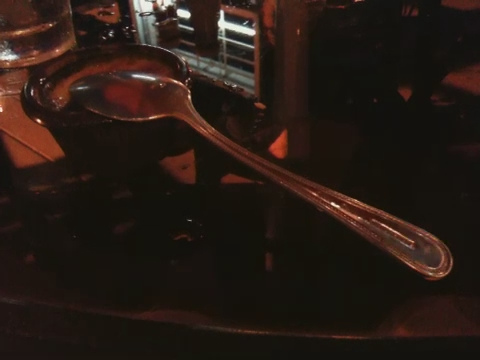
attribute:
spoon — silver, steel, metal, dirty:
[61, 61, 479, 285]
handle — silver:
[247, 145, 459, 286]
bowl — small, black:
[64, 51, 173, 68]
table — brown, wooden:
[30, 139, 66, 158]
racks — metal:
[215, 18, 249, 67]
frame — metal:
[220, 8, 259, 25]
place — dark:
[8, 3, 479, 347]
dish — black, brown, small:
[35, 86, 59, 116]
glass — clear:
[63, 18, 77, 41]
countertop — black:
[108, 212, 232, 289]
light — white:
[173, 5, 192, 22]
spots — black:
[111, 72, 128, 77]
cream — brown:
[67, 72, 87, 84]